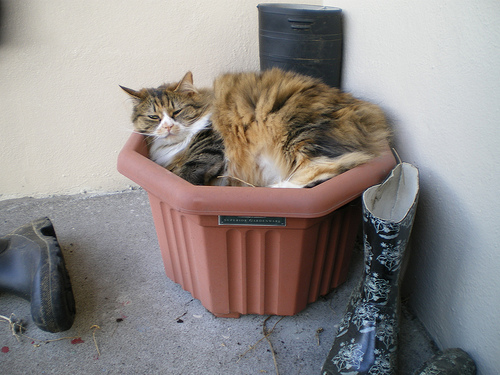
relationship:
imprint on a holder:
[218, 214, 292, 230] [122, 70, 396, 317]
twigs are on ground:
[236, 316, 342, 375] [4, 190, 497, 370]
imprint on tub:
[218, 214, 292, 230] [122, 70, 396, 317]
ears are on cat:
[115, 71, 195, 99] [124, 74, 398, 194]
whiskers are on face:
[132, 125, 202, 136] [121, 101, 206, 146]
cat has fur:
[124, 74, 398, 194] [223, 76, 371, 175]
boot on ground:
[329, 164, 417, 374] [4, 190, 497, 370]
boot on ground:
[6, 217, 75, 335] [4, 190, 497, 370]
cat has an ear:
[124, 74, 398, 194] [176, 71, 196, 90]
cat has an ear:
[124, 74, 398, 194] [119, 84, 144, 101]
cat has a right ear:
[124, 74, 398, 194] [176, 71, 196, 90]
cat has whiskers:
[124, 74, 398, 194] [132, 125, 202, 136]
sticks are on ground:
[236, 316, 342, 375] [4, 190, 497, 370]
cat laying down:
[124, 74, 398, 194] [136, 145, 388, 205]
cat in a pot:
[124, 74, 398, 194] [122, 70, 396, 317]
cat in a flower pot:
[124, 74, 398, 194] [122, 70, 396, 317]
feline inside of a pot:
[124, 74, 398, 194] [122, 70, 396, 317]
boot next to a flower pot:
[329, 164, 417, 374] [122, 70, 396, 317]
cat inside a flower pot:
[124, 74, 398, 194] [122, 70, 396, 317]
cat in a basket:
[124, 74, 398, 194] [122, 70, 396, 317]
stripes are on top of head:
[145, 90, 178, 108] [122, 76, 213, 149]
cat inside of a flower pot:
[124, 74, 398, 194] [122, 70, 396, 317]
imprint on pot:
[218, 214, 292, 230] [122, 70, 396, 317]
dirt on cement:
[15, 292, 437, 375] [4, 190, 497, 370]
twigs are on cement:
[236, 316, 342, 375] [4, 190, 497, 370]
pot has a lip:
[114, 146, 399, 221] [120, 149, 399, 220]